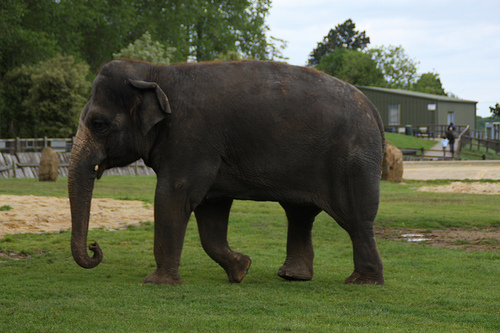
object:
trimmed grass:
[0, 208, 499, 333]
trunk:
[66, 125, 104, 269]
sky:
[187, 0, 500, 118]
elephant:
[63, 57, 404, 287]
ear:
[131, 79, 173, 137]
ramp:
[422, 129, 465, 161]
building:
[354, 85, 478, 163]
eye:
[91, 113, 111, 133]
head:
[76, 59, 162, 179]